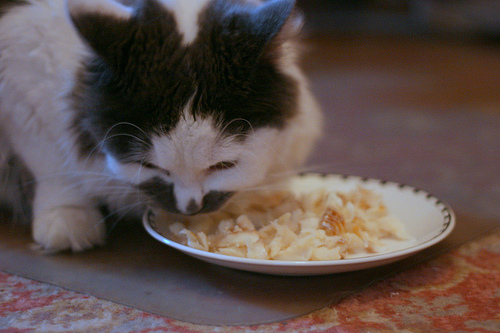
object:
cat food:
[157, 174, 415, 268]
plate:
[128, 162, 470, 281]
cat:
[0, 0, 343, 264]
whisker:
[82, 121, 158, 164]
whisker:
[211, 115, 261, 148]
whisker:
[97, 193, 163, 239]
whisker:
[10, 173, 120, 194]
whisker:
[213, 153, 262, 191]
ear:
[181, 0, 314, 87]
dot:
[185, 195, 202, 215]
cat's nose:
[169, 177, 210, 219]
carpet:
[0, 0, 499, 333]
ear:
[61, 0, 196, 73]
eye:
[137, 158, 175, 180]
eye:
[203, 157, 245, 178]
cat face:
[59, 1, 317, 220]